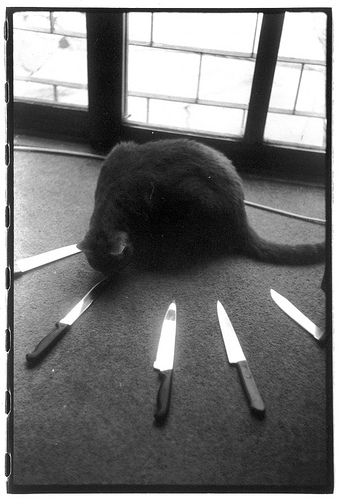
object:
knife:
[25, 276, 110, 364]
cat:
[76, 136, 326, 282]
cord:
[14, 144, 325, 223]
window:
[12, 10, 328, 186]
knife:
[152, 298, 177, 420]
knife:
[216, 298, 266, 413]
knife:
[269, 287, 326, 344]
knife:
[13, 241, 81, 279]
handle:
[25, 321, 71, 363]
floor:
[12, 131, 335, 499]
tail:
[236, 218, 326, 268]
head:
[75, 224, 135, 281]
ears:
[107, 228, 129, 257]